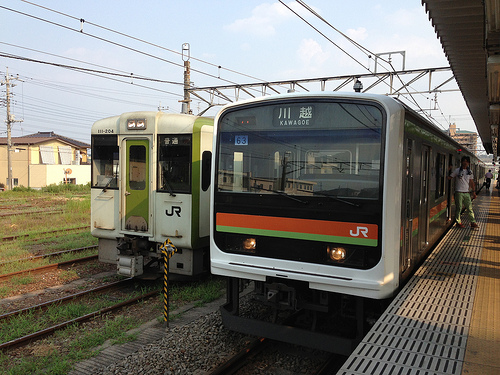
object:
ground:
[1, 196, 328, 373]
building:
[0, 132, 93, 193]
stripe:
[216, 212, 377, 247]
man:
[447, 156, 480, 228]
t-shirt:
[451, 168, 474, 192]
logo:
[166, 206, 182, 218]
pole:
[162, 260, 170, 327]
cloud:
[188, 0, 474, 129]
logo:
[350, 226, 369, 237]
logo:
[163, 204, 187, 216]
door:
[124, 137, 149, 232]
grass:
[1, 181, 224, 375]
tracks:
[0, 214, 160, 348]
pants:
[454, 193, 475, 224]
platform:
[336, 174, 499, 374]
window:
[214, 96, 387, 203]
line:
[0, 0, 266, 130]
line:
[280, 1, 372, 72]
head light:
[244, 238, 256, 251]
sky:
[0, 0, 480, 135]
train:
[90, 112, 215, 279]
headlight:
[330, 248, 347, 262]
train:
[208, 92, 485, 357]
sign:
[277, 105, 311, 125]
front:
[209, 93, 404, 301]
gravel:
[166, 329, 216, 369]